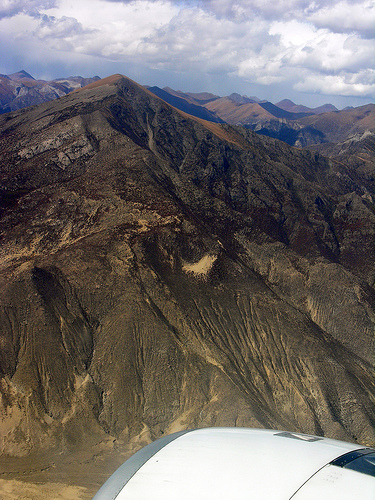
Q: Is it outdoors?
A: Yes, it is outdoors.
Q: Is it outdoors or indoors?
A: It is outdoors.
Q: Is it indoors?
A: No, it is outdoors.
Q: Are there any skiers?
A: No, there are no skiers.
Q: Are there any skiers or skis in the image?
A: No, there are no skiers or skis.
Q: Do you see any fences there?
A: No, there are no fences.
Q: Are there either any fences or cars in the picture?
A: No, there are no fences or cars.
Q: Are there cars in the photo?
A: No, there are no cars.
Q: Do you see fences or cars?
A: No, there are no cars or fences.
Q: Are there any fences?
A: No, there are no fences.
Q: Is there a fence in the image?
A: No, there are no fences.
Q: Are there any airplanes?
A: Yes, there is an airplane.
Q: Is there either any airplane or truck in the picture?
A: Yes, there is an airplane.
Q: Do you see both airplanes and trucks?
A: No, there is an airplane but no trucks.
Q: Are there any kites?
A: No, there are no kites.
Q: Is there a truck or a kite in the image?
A: No, there are no kites or trucks.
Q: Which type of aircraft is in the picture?
A: The aircraft is an airplane.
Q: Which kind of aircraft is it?
A: The aircraft is an airplane.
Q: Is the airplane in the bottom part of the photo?
A: Yes, the airplane is in the bottom of the image.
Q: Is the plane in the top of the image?
A: No, the plane is in the bottom of the image.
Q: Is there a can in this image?
A: No, there are no cans.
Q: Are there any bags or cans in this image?
A: No, there are no cans or bags.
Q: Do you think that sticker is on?
A: Yes, the sticker is on.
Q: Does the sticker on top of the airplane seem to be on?
A: Yes, the sticker is on.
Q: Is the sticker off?
A: No, the sticker is on.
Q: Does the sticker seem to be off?
A: No, the sticker is on.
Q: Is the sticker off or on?
A: The sticker is on.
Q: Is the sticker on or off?
A: The sticker is on.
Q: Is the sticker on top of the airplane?
A: Yes, the sticker is on top of the airplane.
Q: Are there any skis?
A: No, there are no skis.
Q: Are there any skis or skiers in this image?
A: No, there are no skis or skiers.